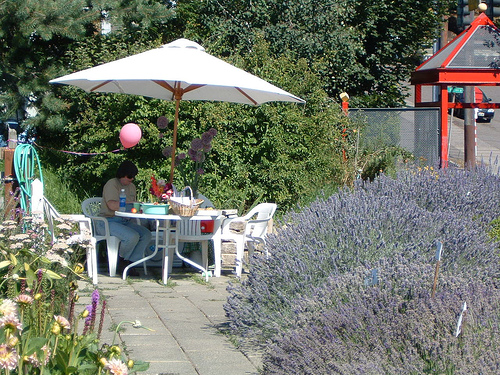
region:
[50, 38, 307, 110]
The white umbrella over the table.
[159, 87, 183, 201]
The brown pole of the umbrella.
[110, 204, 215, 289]
The round center table.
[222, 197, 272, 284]
The white chair on the right.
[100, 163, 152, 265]
The person sitting on the chair.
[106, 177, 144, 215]
The t-shirt the person sitting down is wearing.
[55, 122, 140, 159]
a pink balloon on a string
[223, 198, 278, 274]
a white plastic chair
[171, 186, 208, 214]
a basket on a table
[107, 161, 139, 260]
a woman sitting at a table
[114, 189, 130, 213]
a plastic water bottle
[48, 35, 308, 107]
a white umbrella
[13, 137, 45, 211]
a green garden hose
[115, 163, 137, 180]
a woman with brown hair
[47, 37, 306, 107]
a white table umbrella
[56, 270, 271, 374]
square gray stones on a patio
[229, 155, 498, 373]
lavender bushes in a garden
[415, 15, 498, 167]
a red metal structure in a garden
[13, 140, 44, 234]
a green garden hose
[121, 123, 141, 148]
a light pink inflated party balloon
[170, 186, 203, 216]
a brown wicker party basket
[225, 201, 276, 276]
a white plastic patio chair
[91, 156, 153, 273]
a woman sitting under an umbrella at a table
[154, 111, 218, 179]
a group of purple party balloon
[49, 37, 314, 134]
the umbrella is white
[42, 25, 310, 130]
the umbrella is white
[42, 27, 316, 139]
the umbrella is white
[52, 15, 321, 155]
the umbrella is white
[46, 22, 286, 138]
the umbrella is white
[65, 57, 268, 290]
woman sitting under the umbrella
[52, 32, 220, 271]
woman sitting under the umbrella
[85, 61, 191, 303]
woman sitting under the umbrella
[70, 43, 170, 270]
woman sitting under the umbrella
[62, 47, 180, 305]
woman sitting under the umbrella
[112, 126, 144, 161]
the balloon is pink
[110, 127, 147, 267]
balloon above the woman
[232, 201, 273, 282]
the chair is white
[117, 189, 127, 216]
water on the table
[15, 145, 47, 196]
the hose is green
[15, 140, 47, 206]
the hose is hanging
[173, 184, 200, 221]
basket on the table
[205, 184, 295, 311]
a white patio chair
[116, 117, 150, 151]
pink colored balloon in air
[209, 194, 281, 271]
white colored plastic chair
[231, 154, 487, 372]
green and purple colored bush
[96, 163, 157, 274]
woman sitting down on a white chair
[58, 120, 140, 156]
pink balloon on a pink string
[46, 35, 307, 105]
large open white umbrella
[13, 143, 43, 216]
green garden hose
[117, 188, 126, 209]
clear bottle with a blue label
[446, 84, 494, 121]
small black car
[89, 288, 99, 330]
tall skinny purple flower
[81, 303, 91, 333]
tall skinny purple flower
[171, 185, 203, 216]
basket with a handle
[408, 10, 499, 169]
booth that is glass with red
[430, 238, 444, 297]
small paper sign in the lavender bush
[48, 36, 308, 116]
a large umbrella blocking the sun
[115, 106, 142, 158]
a pink balloon above a womans head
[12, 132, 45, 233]
green water hose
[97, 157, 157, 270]
a woman sitting